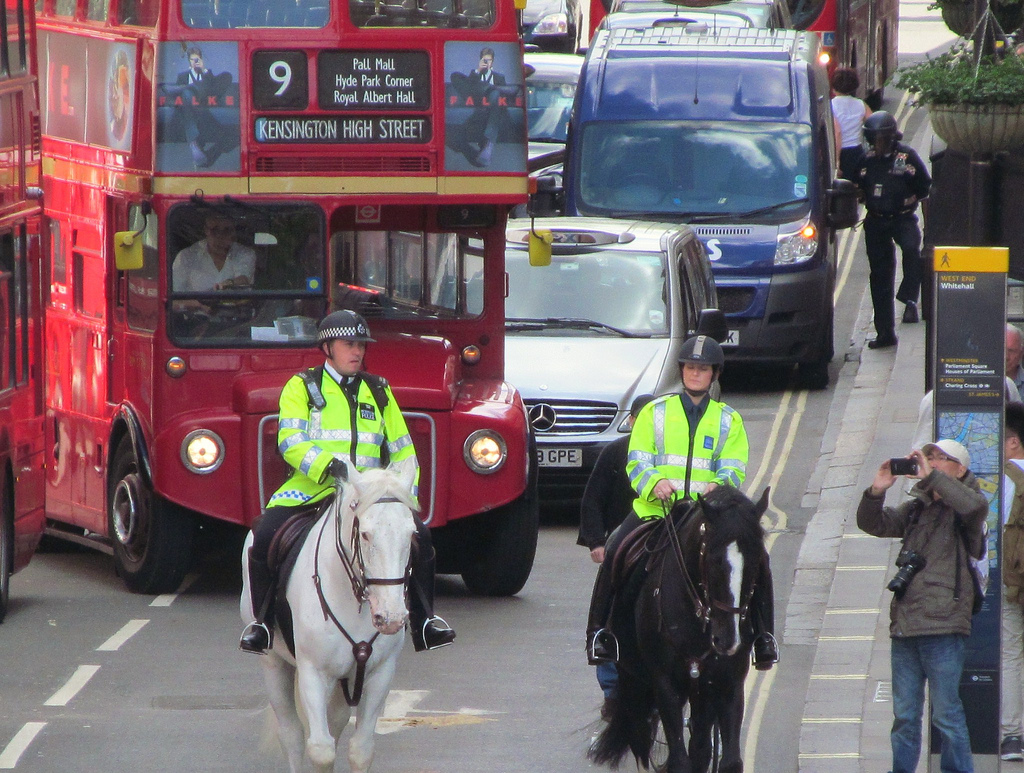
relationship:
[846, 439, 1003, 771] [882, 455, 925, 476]
man holding camera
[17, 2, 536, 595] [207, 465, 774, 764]
bus behind horses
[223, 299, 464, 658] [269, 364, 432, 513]
man wearing jacket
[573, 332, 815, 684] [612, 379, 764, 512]
woman wearing jacket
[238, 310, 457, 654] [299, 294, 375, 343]
man wearing helmet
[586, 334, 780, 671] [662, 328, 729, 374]
woman wearing helmet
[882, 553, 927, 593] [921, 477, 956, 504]
camera around neck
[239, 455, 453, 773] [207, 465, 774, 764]
horse behind horses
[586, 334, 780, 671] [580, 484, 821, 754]
woman riding horse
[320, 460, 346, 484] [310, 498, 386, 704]
hand gripping rein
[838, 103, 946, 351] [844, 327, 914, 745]
policeman standing on sidewalk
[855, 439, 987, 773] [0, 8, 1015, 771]
man takes photo